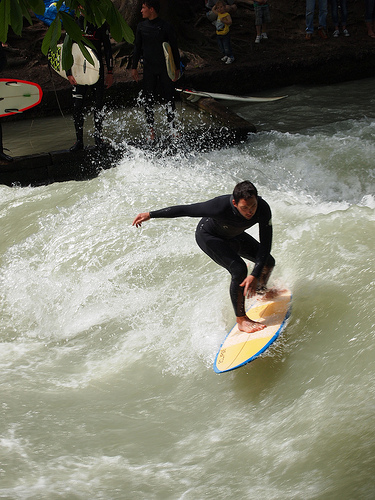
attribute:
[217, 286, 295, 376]
board — long, yellow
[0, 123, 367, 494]
water — green, brown, deep, waving, high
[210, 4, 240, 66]
kid — tiny, standing, white, watching, small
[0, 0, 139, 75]
tree — green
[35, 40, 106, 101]
surfboard — white, long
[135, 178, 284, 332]
man — tall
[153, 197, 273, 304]
wet suit — black